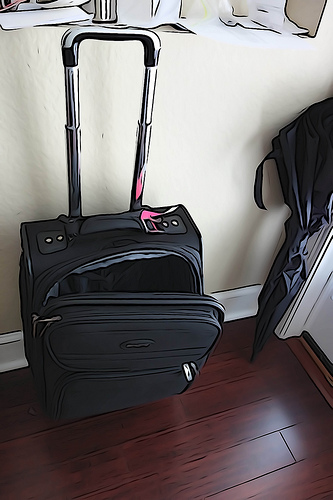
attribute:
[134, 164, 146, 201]
reflection — white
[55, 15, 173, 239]
handle — black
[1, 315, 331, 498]
flooring — wooden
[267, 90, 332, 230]
handle — black, broad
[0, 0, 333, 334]
wall — cream colored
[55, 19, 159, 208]
handle — retractable, silver, extended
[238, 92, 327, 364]
umbrella — black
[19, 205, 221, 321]
top — open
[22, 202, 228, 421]
suitcase — black, canvas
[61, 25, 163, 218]
handle — shiny, metal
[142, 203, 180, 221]
tag — pink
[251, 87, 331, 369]
black umbrella — long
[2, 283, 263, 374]
molding — white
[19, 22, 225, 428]
suitcase — black, open, leaning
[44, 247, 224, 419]
main compartment — unzippered, emptiness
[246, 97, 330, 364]
black umbrella — big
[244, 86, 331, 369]
umbrella — black, leaning, dark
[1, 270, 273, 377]
baseboards — white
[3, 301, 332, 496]
floorboards — dark, wooden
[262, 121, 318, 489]
umbrella — dark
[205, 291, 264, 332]
floor board — white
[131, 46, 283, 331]
wall — cream-colored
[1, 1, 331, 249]
wall — beige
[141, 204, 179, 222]
label — fuchsia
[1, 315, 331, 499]
floor — dark brown, planks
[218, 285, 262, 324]
baseboard — white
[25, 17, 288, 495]
suitcase — empty, black, open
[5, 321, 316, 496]
floor — dark, wood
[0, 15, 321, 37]
edge — bottom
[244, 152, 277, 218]
strap — curved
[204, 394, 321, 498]
light — reflected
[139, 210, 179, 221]
tag — pink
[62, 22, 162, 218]
holder — metal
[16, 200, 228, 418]
bag — black, open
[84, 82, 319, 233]
wall — tan